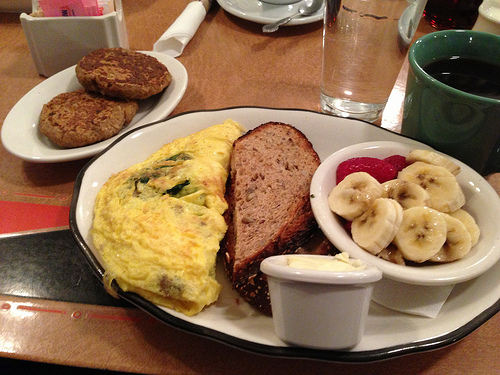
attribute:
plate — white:
[65, 100, 473, 370]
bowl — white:
[309, 141, 484, 283]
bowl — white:
[313, 136, 479, 297]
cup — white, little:
[260, 250, 375, 359]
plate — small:
[6, 45, 189, 165]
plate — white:
[5, 46, 198, 192]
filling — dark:
[128, 148, 201, 214]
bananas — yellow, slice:
[344, 163, 471, 258]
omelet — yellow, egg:
[85, 121, 235, 294]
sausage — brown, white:
[31, 49, 174, 143]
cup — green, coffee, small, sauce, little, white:
[400, 23, 499, 158]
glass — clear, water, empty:
[311, 2, 393, 126]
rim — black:
[417, 29, 496, 97]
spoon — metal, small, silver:
[262, 0, 323, 40]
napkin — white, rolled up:
[156, 2, 217, 51]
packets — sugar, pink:
[33, 1, 104, 19]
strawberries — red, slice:
[338, 153, 400, 177]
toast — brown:
[231, 100, 321, 271]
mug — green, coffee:
[400, 24, 494, 170]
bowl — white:
[258, 0, 301, 11]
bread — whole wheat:
[224, 120, 316, 269]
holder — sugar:
[12, 14, 134, 75]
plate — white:
[71, 110, 500, 368]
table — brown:
[191, 24, 321, 102]